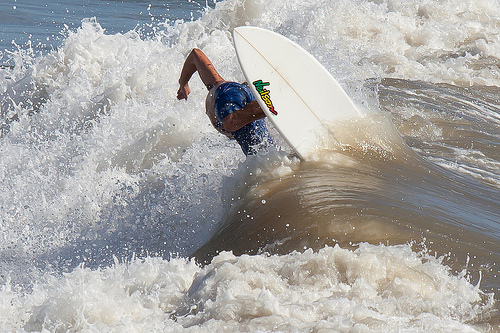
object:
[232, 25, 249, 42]
tip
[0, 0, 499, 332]
ocean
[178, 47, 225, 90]
arm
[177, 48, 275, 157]
man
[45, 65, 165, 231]
waves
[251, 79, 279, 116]
writing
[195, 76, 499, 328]
waves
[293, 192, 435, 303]
water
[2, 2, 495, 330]
wave.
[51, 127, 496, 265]
water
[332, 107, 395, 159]
splash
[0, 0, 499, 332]
water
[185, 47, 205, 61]
elbow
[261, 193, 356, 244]
wave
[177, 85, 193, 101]
hand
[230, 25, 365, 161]
board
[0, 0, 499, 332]
wave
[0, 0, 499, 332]
white water